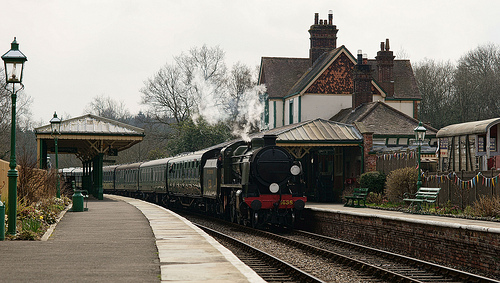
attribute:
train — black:
[46, 143, 304, 232]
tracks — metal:
[199, 207, 491, 282]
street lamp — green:
[3, 35, 25, 239]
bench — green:
[70, 179, 87, 208]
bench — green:
[402, 188, 444, 210]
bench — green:
[342, 186, 372, 209]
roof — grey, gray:
[252, 50, 422, 91]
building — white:
[255, 16, 424, 188]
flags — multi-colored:
[421, 175, 499, 191]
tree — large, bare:
[151, 49, 242, 150]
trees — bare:
[422, 54, 493, 124]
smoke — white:
[186, 69, 267, 136]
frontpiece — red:
[249, 194, 306, 208]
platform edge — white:
[217, 250, 254, 282]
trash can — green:
[72, 192, 83, 212]